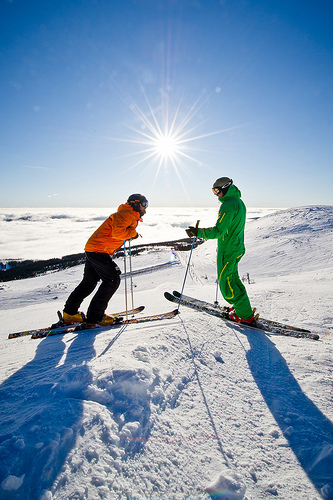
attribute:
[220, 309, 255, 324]
foot — skier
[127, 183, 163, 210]
hat — black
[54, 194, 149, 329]
person — leaning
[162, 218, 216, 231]
hand — skier's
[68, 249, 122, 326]
pants — black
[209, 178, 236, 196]
goggles — reflective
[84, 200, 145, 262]
jacket — orange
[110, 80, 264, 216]
sun — very bright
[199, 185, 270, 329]
suit — green, snow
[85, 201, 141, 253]
jacket — orange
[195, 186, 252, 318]
coveralls — green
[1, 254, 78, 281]
trees — line of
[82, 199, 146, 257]
jacket — orange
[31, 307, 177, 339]
ski — multi colored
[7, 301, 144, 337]
ski — multi colored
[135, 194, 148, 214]
face — skier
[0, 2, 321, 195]
sky — blue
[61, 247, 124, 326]
pants — black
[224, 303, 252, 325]
ski boots — red